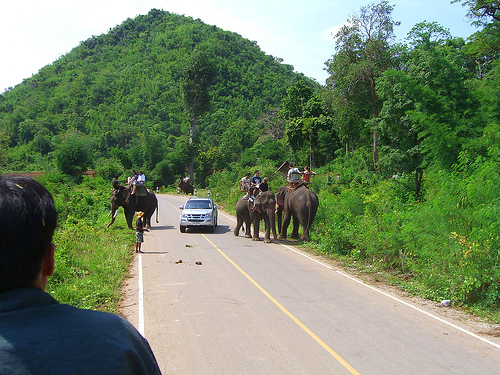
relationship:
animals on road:
[107, 167, 319, 255] [113, 185, 450, 364]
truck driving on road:
[177, 196, 219, 232] [115, 190, 485, 372]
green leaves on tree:
[404, 80, 433, 120] [364, 42, 484, 209]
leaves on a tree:
[89, 72, 118, 102] [90, 69, 121, 104]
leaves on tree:
[68, 138, 85, 166] [55, 135, 94, 179]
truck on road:
[179, 197, 217, 233] [115, 190, 485, 372]